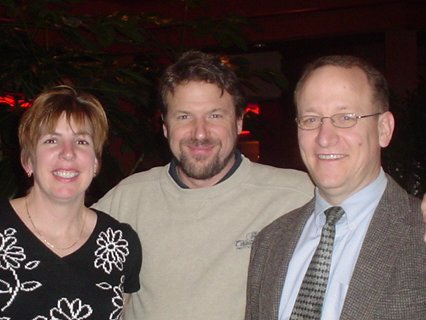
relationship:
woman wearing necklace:
[3, 81, 153, 318] [22, 194, 88, 249]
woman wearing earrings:
[3, 81, 153, 318] [25, 170, 98, 178]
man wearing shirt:
[84, 50, 317, 318] [101, 142, 322, 317]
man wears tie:
[241, 63, 412, 260] [279, 202, 363, 313]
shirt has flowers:
[3, 192, 143, 318] [0, 225, 25, 269]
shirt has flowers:
[3, 192, 143, 318] [47, 294, 93, 318]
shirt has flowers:
[3, 192, 143, 318] [107, 273, 126, 318]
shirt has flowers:
[3, 192, 143, 318] [92, 227, 130, 272]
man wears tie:
[240, 52, 424, 318] [289, 206, 344, 318]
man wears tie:
[84, 50, 317, 318] [289, 206, 344, 318]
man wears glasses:
[240, 52, 424, 318] [292, 111, 382, 128]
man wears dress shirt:
[291, 59, 421, 318] [297, 194, 374, 314]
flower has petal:
[92, 224, 132, 262] [113, 227, 120, 240]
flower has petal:
[0, 227, 38, 317] [71, 295, 81, 315]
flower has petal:
[48, 297, 95, 318] [2, 234, 16, 247]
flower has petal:
[95, 275, 122, 318] [112, 295, 124, 307]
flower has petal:
[95, 275, 122, 318] [106, 250, 114, 263]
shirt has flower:
[3, 192, 143, 318] [92, 224, 132, 262]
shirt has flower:
[3, 192, 143, 318] [0, 227, 38, 317]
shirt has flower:
[3, 192, 143, 318] [48, 297, 95, 318]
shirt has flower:
[3, 192, 143, 318] [95, 275, 122, 318]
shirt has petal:
[3, 192, 143, 318] [113, 228, 123, 238]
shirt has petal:
[3, 192, 143, 318] [116, 239, 127, 246]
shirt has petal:
[3, 192, 143, 318] [111, 226, 119, 241]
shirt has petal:
[3, 192, 143, 318] [99, 228, 108, 242]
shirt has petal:
[3, 192, 143, 318] [94, 245, 104, 254]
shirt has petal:
[3, 192, 143, 318] [108, 250, 111, 260]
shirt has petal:
[3, 192, 143, 318] [3, 233, 18, 249]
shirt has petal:
[3, 192, 143, 318] [5, 245, 23, 253]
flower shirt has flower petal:
[1, 197, 143, 318] [2, 254, 20, 270]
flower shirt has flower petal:
[1, 197, 143, 318] [6, 251, 26, 261]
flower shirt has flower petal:
[1, 197, 143, 318] [0, 237, 15, 250]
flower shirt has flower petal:
[1, 197, 143, 318] [57, 297, 72, 318]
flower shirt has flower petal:
[1, 197, 143, 318] [73, 305, 93, 318]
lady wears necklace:
[0, 77, 141, 313] [23, 198, 99, 255]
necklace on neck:
[23, 198, 99, 255] [25, 188, 85, 228]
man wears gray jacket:
[275, 54, 416, 315] [260, 201, 415, 316]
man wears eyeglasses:
[240, 52, 424, 318] [289, 108, 386, 128]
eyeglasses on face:
[289, 108, 386, 128] [287, 79, 378, 188]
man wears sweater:
[151, 57, 260, 215] [144, 182, 260, 307]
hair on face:
[181, 158, 218, 173] [153, 87, 247, 170]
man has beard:
[84, 50, 317, 318] [179, 137, 222, 178]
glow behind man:
[217, 55, 260, 159] [84, 50, 317, 318]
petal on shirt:
[113, 240, 128, 257] [0, 82, 142, 319]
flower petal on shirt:
[91, 230, 134, 271] [3, 192, 143, 318]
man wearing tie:
[240, 52, 424, 318] [284, 197, 372, 318]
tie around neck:
[284, 197, 372, 318] [313, 161, 386, 217]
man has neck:
[240, 52, 424, 318] [313, 161, 386, 217]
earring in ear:
[26, 170, 33, 176] [18, 140, 34, 179]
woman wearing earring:
[3, 81, 153, 318] [26, 170, 33, 176]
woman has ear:
[3, 81, 153, 318] [18, 140, 34, 179]